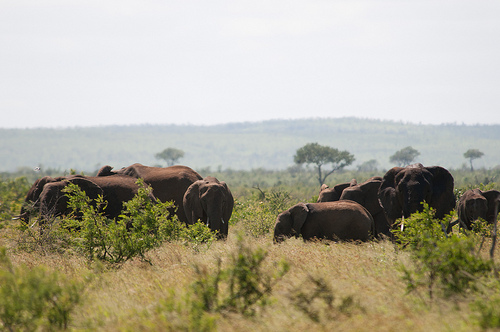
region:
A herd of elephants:
[284, 157, 475, 262]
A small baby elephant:
[270, 195, 384, 249]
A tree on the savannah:
[288, 136, 354, 193]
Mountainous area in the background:
[158, 108, 389, 169]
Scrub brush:
[102, 232, 285, 330]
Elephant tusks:
[9, 204, 67, 241]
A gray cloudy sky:
[225, 10, 473, 99]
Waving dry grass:
[270, 234, 392, 291]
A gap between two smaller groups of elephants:
[225, 166, 285, 244]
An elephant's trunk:
[201, 187, 227, 235]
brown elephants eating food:
[57, 160, 398, 301]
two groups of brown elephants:
[36, 133, 426, 330]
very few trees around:
[35, 92, 485, 232]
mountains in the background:
[24, 90, 486, 296]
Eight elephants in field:
[40, 145, 496, 289]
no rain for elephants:
[33, 167, 455, 329]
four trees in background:
[33, 140, 488, 265]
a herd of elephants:
[47, 152, 477, 282]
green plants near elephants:
[61, 182, 476, 324]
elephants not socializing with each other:
[21, 169, 458, 281]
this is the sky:
[158, 19, 298, 79]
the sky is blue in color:
[199, 34, 284, 79]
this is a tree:
[295, 142, 354, 181]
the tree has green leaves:
[138, 211, 155, 226]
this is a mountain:
[223, 118, 282, 149]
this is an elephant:
[280, 201, 361, 236]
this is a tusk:
[376, 197, 383, 207]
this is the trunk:
[208, 214, 221, 229]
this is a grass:
[109, 277, 146, 297]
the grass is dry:
[298, 240, 320, 267]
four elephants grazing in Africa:
[35, 143, 257, 288]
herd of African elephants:
[23, 96, 483, 271]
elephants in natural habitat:
[27, 123, 471, 261]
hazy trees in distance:
[47, 82, 429, 170]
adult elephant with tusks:
[373, 149, 459, 270]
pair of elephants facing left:
[14, 136, 158, 269]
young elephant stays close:
[257, 186, 381, 251]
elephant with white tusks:
[172, 169, 256, 254]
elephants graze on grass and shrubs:
[30, 196, 410, 326]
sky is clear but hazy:
[66, 18, 416, 125]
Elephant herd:
[16, 155, 489, 262]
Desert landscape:
[27, 111, 419, 311]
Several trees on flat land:
[264, 112, 497, 193]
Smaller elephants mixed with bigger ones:
[265, 172, 480, 265]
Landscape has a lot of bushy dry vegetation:
[105, 149, 417, 319]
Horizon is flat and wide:
[49, 99, 458, 176]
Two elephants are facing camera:
[161, 163, 482, 278]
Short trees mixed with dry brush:
[59, 178, 203, 298]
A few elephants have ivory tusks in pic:
[170, 171, 465, 261]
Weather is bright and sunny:
[241, 46, 498, 286]